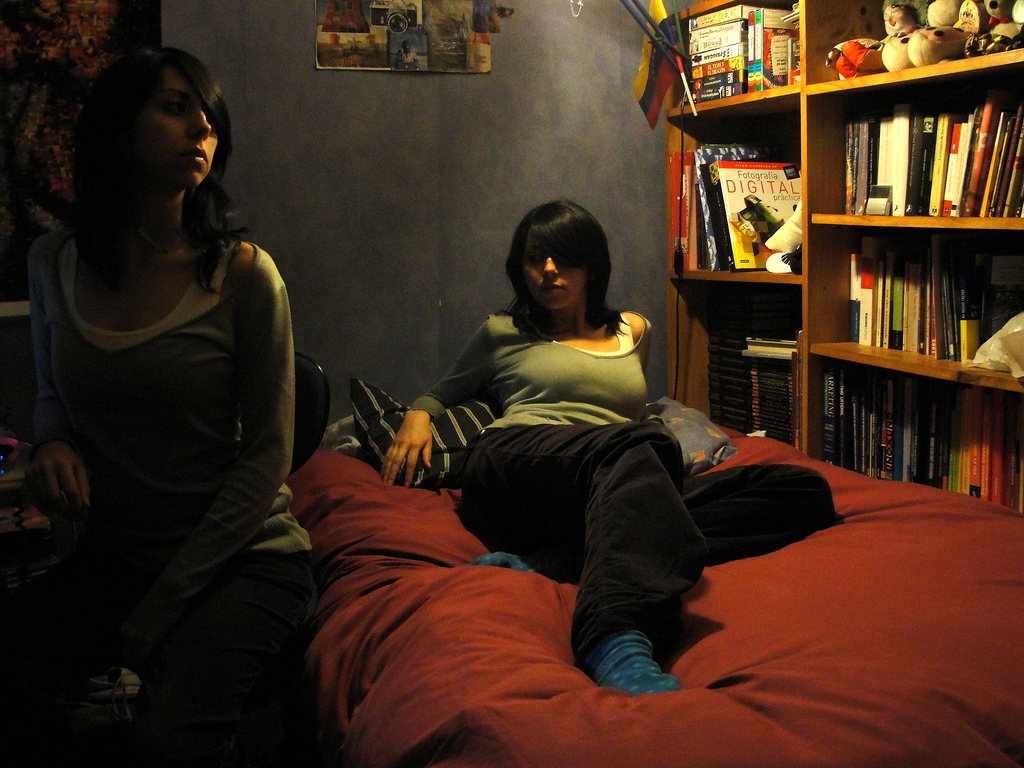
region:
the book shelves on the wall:
[651, 1, 1021, 495]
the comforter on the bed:
[299, 410, 1020, 766]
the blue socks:
[479, 540, 683, 702]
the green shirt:
[0, 235, 672, 644]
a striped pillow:
[343, 366, 525, 488]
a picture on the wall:
[305, 6, 521, 86]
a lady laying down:
[379, 197, 841, 695]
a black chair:
[297, 355, 342, 476]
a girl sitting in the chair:
[25, 32, 323, 754]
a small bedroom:
[6, 9, 1022, 763]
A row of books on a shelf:
[808, 98, 1021, 210]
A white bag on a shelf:
[968, 309, 1022, 370]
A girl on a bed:
[383, 198, 843, 702]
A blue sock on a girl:
[596, 628, 685, 692]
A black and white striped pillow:
[352, 373, 493, 484]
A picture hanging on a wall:
[305, 0, 498, 81]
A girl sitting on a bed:
[29, 41, 314, 753]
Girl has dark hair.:
[499, 190, 646, 347]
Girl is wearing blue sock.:
[593, 636, 689, 713]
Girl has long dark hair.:
[68, 69, 259, 259]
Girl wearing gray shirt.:
[18, 263, 307, 562]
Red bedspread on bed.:
[347, 442, 974, 765]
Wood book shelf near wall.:
[707, 79, 1017, 463]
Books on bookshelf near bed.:
[834, 240, 1018, 345]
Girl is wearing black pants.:
[149, 562, 296, 765]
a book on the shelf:
[930, 192, 1020, 320]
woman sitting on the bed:
[358, 181, 845, 698]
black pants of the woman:
[450, 393, 847, 632]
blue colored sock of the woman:
[580, 631, 685, 704]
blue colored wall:
[147, 10, 698, 437]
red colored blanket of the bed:
[289, 413, 1007, 764]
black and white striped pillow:
[346, 354, 502, 468]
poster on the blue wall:
[305, 10, 496, 88]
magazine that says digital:
[703, 138, 815, 274]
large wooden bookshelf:
[644, 17, 1021, 520]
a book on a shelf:
[942, 107, 1018, 191]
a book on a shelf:
[906, 241, 926, 375]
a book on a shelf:
[895, 262, 915, 355]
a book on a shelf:
[854, 373, 883, 466]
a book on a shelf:
[713, 154, 759, 276]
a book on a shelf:
[731, 344, 780, 431]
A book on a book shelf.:
[710, 160, 803, 271]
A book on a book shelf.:
[692, 141, 795, 271]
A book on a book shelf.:
[666, 149, 696, 267]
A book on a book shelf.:
[840, 119, 854, 217]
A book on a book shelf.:
[855, 119, 869, 218]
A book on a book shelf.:
[928, 111, 952, 214]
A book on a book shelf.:
[958, 98, 998, 217]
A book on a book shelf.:
[857, 235, 878, 346]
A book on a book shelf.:
[818, 367, 839, 466]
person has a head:
[509, 199, 602, 311]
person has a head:
[74, 48, 221, 200]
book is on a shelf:
[895, 116, 909, 212]